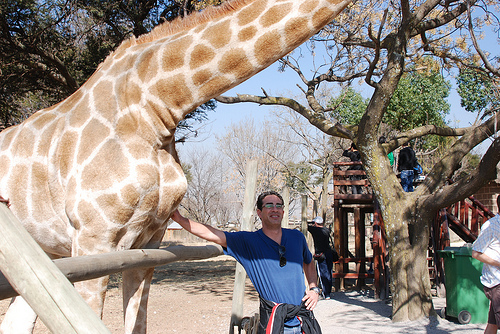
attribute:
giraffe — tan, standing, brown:
[3, 2, 371, 332]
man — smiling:
[174, 189, 327, 331]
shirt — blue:
[225, 224, 316, 328]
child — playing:
[345, 135, 367, 193]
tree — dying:
[215, 8, 500, 324]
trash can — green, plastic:
[434, 247, 494, 323]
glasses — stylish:
[259, 201, 284, 209]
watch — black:
[309, 287, 322, 295]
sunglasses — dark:
[273, 243, 289, 268]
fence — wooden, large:
[1, 161, 344, 332]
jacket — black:
[255, 292, 323, 331]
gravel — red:
[1, 257, 317, 333]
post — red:
[367, 209, 394, 291]